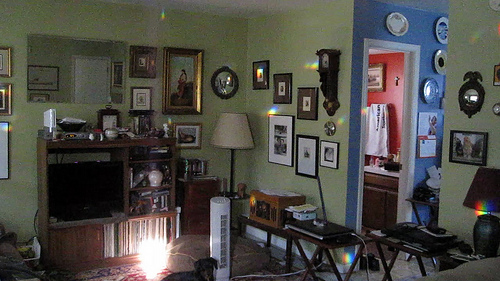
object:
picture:
[295, 85, 319, 122]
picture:
[272, 72, 292, 104]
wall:
[247, 14, 350, 48]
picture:
[251, 61, 271, 91]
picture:
[320, 139, 340, 169]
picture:
[297, 134, 320, 177]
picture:
[267, 113, 294, 168]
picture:
[161, 45, 203, 114]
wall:
[2, 5, 247, 245]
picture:
[130, 84, 152, 115]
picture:
[174, 121, 202, 149]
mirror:
[25, 33, 126, 104]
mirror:
[458, 71, 484, 118]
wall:
[437, 3, 497, 248]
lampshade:
[211, 111, 253, 149]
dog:
[162, 256, 218, 280]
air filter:
[209, 195, 231, 278]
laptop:
[289, 216, 354, 241]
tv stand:
[283, 227, 368, 278]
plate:
[387, 10, 410, 37]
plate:
[435, 16, 448, 44]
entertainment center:
[36, 129, 180, 270]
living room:
[0, 5, 498, 278]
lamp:
[210, 110, 254, 198]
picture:
[449, 130, 489, 167]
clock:
[316, 49, 342, 118]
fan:
[208, 184, 325, 278]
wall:
[347, 1, 448, 265]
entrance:
[351, 29, 427, 256]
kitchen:
[378, 46, 437, 179]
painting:
[0, 46, 12, 77]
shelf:
[178, 177, 219, 237]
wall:
[367, 53, 402, 169]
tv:
[48, 160, 125, 220]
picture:
[129, 44, 158, 78]